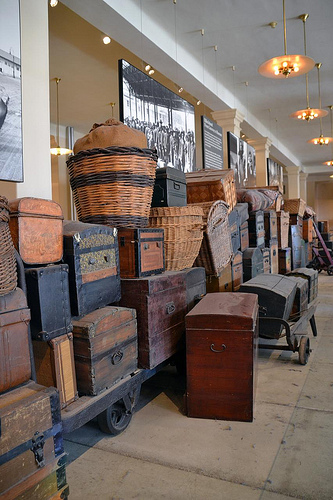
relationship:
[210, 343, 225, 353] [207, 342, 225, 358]
handle a handle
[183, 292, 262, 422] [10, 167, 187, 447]
box in front of pile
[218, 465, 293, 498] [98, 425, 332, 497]
lines on pavement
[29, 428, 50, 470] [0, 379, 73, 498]
clasp on a trunk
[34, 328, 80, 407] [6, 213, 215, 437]
suitcase in pile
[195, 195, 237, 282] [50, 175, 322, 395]
basket in a pile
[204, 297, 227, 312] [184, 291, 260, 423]
dust on box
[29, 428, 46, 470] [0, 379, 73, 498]
clasp on trunk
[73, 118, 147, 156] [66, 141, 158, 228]
bag in basket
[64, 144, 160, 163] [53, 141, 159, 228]
top of basket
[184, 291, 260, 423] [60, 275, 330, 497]
box on ground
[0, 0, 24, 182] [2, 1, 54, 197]
picture on wall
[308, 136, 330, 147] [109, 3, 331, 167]
light hanging from ceiling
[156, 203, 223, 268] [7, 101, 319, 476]
basket in a pile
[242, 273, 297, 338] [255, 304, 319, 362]
trunk on cart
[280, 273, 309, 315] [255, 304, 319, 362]
trunk on cart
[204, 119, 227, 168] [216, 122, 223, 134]
white words on black surface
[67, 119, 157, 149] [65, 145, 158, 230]
bag in basket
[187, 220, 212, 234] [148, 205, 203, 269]
handle on basket